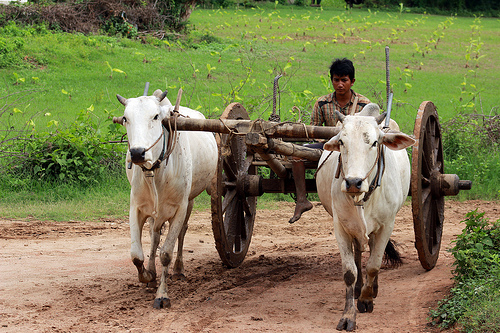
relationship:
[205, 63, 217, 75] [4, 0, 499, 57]
plant growing in field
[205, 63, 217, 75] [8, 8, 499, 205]
plant growing in field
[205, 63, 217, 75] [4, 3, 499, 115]
plant growing in field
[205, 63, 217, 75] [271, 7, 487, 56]
plant growing in field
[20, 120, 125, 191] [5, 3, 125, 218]
plant growing in field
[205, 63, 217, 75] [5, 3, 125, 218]
plant growing in field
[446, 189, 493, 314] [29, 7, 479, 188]
plant growing in field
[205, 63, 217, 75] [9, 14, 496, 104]
plant growing in field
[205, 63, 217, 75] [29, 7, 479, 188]
plant growing in field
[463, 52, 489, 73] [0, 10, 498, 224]
plant growing in field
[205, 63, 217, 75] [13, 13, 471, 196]
plant growing in field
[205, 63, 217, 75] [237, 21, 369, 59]
plant growing in field